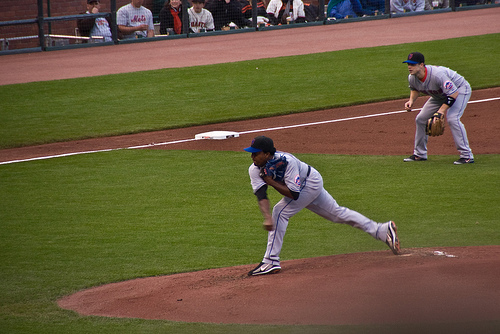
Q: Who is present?
A: Players.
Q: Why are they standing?
A: To play.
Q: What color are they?
A: White.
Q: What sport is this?
A: Baseball.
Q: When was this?
A: Daytime.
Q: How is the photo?
A: Clear.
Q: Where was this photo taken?
A: At a baseball game.